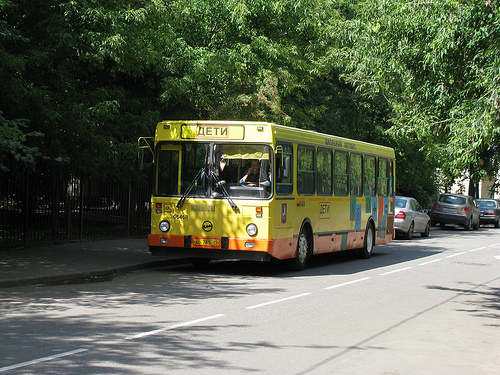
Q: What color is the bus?
A: Yellow.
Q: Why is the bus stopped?
A: Pulling over at next stop.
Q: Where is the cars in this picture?
A: Behind the bus.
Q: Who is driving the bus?
A: Bus driver.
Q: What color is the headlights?
A: Clear.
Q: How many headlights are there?
A: 2.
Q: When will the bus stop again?
A: Next stop.